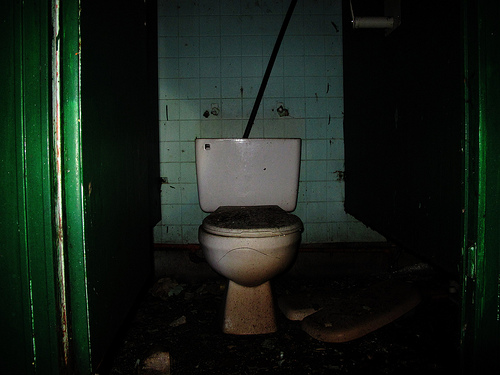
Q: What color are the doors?
A: Green.